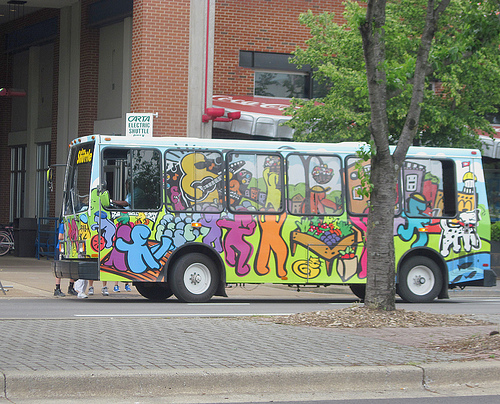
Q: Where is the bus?
A: On the road.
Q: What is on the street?
A: A bus.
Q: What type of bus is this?
A: A passenger bus.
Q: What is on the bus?
A: Colorful painting.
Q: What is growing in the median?
A: A tree.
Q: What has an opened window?
A: The bus.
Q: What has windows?
A: The passenger bus.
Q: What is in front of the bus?
A: The tree.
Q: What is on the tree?
A: Green leaves.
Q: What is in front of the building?
A: The bus.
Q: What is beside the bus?
A: The tree.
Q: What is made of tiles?
A: The pavement.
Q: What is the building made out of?
A: Bricks.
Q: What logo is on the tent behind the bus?
A: Coca-Cola.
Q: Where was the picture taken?
A: A city.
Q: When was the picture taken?
A: Daytime.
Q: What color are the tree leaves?
A: Green.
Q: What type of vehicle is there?
A: A bus.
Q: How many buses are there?
A: One.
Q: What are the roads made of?
A: Asphalt.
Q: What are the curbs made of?
A: Cement.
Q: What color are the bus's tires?
A: Black.